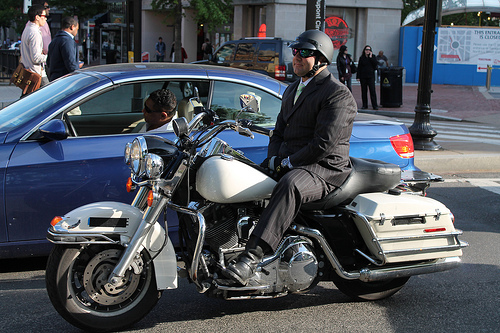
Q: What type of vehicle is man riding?
A: Bike.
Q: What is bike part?
A: Tire.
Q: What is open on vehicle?
A: Window.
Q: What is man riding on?
A: Motorcycle.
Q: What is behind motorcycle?
A: Blue car.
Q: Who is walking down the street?
A: The people.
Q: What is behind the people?
A: Buildings.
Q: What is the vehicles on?
A: The street.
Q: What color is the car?
A: Blue.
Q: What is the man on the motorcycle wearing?
A: A suit.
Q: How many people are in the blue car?
A: One.